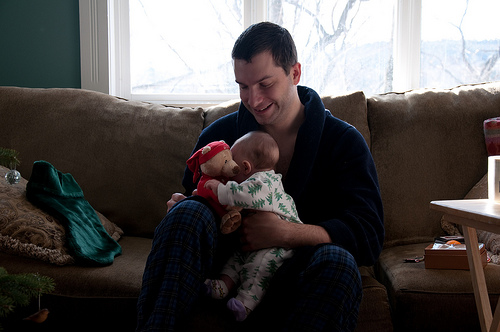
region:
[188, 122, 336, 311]
The baby is hugging a teddy bear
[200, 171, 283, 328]
The baby has on a christmas themed pajama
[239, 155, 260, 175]
The ear of the baby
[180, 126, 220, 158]
The teddy bear is wearing a hat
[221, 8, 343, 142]
The man is smiling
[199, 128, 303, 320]
young baby in a white and green onesie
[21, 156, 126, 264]
small green velvet blanket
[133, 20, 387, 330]
man smiling and holding a baby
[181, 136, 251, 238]
small teddy bear wearing red pajamas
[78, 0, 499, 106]
long window with white wooden frame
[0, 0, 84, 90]
green painted wall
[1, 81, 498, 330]
beige cloth couch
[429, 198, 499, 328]
light wooden tv dinner tray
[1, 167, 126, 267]
brown brocade pillow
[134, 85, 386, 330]
blue plaid pajamas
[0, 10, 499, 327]
man is sitting down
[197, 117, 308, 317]
this is a baby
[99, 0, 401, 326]
man is holding a baby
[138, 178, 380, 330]
man wearing blue pants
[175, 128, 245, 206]
this is a teddy bear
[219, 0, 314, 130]
the man is smiling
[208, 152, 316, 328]
a white and green onesie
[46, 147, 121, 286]
a pillow on couch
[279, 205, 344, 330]
a man wearing blue pants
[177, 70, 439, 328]
a man wearing a robe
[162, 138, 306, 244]
a bear wearing a hat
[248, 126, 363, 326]
a baby wearing pjs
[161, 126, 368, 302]
a baby hugging a bear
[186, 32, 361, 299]
a man holidng baby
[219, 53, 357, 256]
a man with baby in lap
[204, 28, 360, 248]
a man that is smiling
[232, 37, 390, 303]
a man wearing a robe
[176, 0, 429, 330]
a man sitting on couch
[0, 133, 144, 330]
a couch with pillow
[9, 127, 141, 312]
a pillow on couch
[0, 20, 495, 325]
man sitting on a couch holding a baby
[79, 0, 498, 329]
glass window behind man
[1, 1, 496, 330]
dark brown couch in front of window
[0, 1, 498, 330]
green painted wall behind couch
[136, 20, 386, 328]
man on the couch holding a baby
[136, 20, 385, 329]
Man sitting on brown couch.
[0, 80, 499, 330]
Brown couch in living room.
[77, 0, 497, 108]
White-framed window in living room.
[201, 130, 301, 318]
Baby on man's lap in living room.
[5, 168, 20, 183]
Silver-colored ball hanging from tree in living room.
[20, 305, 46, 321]
Bird ornament hanging from tree in living room.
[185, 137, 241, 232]
Teddy bear being hugged by baby.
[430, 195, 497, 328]
Brown table in living room.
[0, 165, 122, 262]
Pillow on couch next to a Christmas tree.